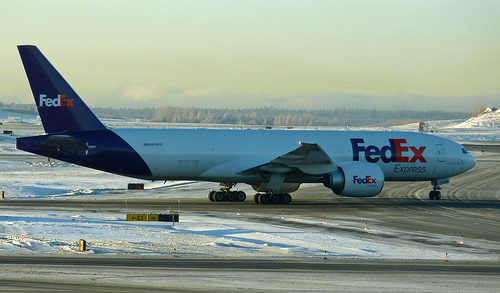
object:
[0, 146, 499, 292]
runway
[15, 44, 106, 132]
fin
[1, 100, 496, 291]
landscape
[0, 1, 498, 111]
sky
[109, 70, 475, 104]
clouds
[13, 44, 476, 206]
airplane